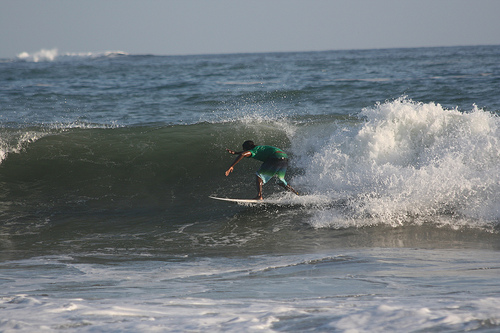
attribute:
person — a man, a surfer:
[223, 136, 308, 201]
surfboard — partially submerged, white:
[204, 189, 335, 208]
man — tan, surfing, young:
[220, 135, 300, 202]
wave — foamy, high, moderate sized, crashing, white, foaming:
[3, 96, 500, 234]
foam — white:
[280, 93, 499, 238]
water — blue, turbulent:
[3, 47, 499, 332]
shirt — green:
[247, 141, 288, 163]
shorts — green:
[256, 153, 289, 187]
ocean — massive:
[0, 42, 498, 332]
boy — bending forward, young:
[223, 138, 299, 205]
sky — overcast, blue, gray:
[0, 0, 499, 56]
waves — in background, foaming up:
[16, 41, 155, 67]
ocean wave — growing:
[4, 92, 499, 241]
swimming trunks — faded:
[257, 151, 290, 186]